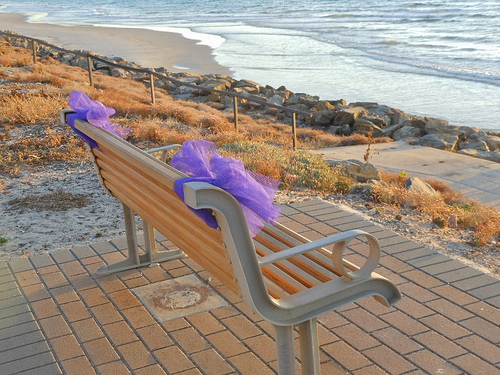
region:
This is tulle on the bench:
[47, 79, 279, 227]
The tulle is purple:
[63, 95, 278, 227]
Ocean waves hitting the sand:
[8, 1, 263, 89]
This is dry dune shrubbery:
[6, 46, 493, 246]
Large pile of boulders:
[76, 47, 498, 152]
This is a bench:
[65, 105, 404, 373]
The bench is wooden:
[58, 97, 410, 369]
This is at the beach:
[4, 2, 495, 176]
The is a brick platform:
[2, 180, 498, 371]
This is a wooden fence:
[7, 81, 312, 149]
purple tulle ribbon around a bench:
[170, 140, 277, 238]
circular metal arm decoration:
[339, 235, 378, 277]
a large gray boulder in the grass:
[402, 177, 431, 199]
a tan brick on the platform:
[80, 286, 107, 306]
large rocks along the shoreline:
[0, 27, 497, 159]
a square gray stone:
[131, 270, 226, 321]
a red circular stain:
[151, 282, 206, 308]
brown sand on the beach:
[0, 7, 231, 79]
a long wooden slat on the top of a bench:
[75, 116, 181, 191]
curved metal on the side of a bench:
[185, 181, 397, 373]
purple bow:
[50, 70, 116, 149]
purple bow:
[157, 154, 274, 231]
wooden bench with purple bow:
[22, 70, 380, 310]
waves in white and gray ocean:
[358, 14, 457, 61]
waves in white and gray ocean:
[382, 22, 434, 52]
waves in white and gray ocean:
[430, 39, 480, 94]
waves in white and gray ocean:
[245, 9, 292, 47]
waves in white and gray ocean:
[288, 25, 323, 57]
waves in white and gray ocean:
[320, 13, 387, 90]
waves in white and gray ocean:
[271, 18, 329, 65]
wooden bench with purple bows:
[35, 73, 366, 324]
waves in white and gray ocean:
[244, 21, 276, 51]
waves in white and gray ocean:
[454, 25, 496, 86]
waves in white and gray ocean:
[322, 12, 349, 30]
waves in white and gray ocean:
[230, 26, 290, 67]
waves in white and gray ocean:
[332, 62, 380, 119]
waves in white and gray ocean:
[357, 11, 435, 79]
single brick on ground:
[72, 317, 102, 339]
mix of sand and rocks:
[29, 216, 78, 238]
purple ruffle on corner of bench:
[165, 145, 265, 225]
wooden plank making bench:
[78, 123, 174, 178]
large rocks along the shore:
[378, 112, 448, 137]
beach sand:
[130, 39, 197, 55]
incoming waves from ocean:
[270, 8, 394, 69]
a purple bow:
[173, 140, 281, 231]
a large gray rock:
[413, 126, 457, 151]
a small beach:
[0, 5, 225, 81]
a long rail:
[0, 32, 315, 149]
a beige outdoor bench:
[54, 95, 401, 372]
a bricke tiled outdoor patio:
[1, 196, 496, 372]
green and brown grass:
[223, 133, 341, 186]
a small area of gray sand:
[1, 205, 88, 250]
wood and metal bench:
[54, 74, 405, 372]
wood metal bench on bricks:
[23, 78, 420, 373]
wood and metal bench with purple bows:
[52, 78, 402, 329]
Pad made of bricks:
[4, 258, 211, 368]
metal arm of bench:
[180, 172, 425, 329]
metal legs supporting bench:
[105, 194, 336, 374]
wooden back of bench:
[85, 142, 257, 302]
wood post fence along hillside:
[15, 31, 303, 149]